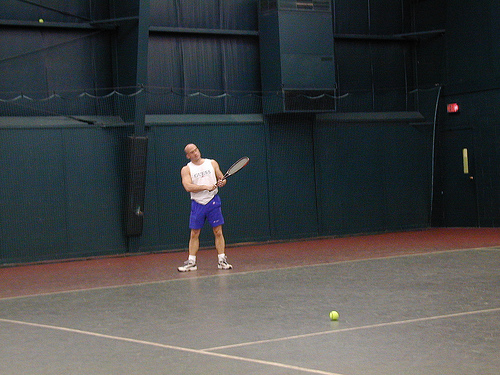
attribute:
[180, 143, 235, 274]
man — bald, waiting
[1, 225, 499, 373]
ground — white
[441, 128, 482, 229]
door — green, black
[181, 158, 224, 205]
shirt — sleeveless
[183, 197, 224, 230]
shorts — purple, blue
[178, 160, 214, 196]
arm — muscular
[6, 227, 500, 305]
floor — red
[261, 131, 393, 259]
wall — green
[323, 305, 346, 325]
tennis ball — yellow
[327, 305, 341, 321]
tennis ball — yellow